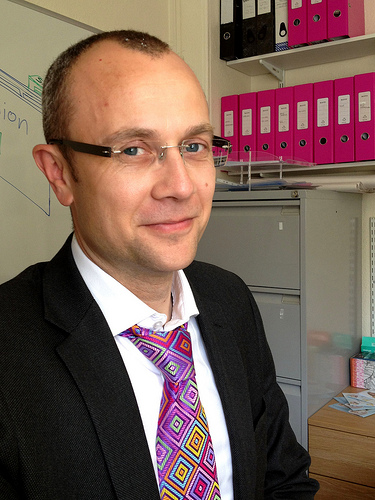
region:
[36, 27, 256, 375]
man posing for a PICTURE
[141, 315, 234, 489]
the tie is multiclored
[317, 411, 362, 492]
the table is wooden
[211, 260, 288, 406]
the coat is black in color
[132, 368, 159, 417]
the shirt is white in color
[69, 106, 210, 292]
the man is smiling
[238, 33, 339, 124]
files are arranged on shelf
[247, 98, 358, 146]
files are oink in color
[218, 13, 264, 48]
files are black incolor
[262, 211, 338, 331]
the cupboard is metallic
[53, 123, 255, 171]
A person wearing black color frame specs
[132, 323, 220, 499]
A person wearing multi color tie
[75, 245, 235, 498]
A person wearing white color shirt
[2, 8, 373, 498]
A person wearing black color suit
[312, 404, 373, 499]
Brown color wooden table kept near the wall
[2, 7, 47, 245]
White color board attached in the wall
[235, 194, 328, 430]
Grey color metal cupboard with racks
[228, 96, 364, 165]
Files kept in the rack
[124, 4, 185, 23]
Cream color wall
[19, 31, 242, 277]
Head of the person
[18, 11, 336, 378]
this is a man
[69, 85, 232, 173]
the man has glasses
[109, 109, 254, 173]
the man has green eyes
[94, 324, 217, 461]
the man has as necktie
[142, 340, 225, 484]
the necktie is colorful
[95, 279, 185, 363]
the man has a collared shirt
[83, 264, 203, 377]
the collared shirt is white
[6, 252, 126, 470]
this is a suit jacket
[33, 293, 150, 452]
the suit jacket is black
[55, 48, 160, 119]
the man is balding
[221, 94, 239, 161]
pink binder on shelf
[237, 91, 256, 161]
pink binder on shelf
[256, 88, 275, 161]
pink binder on shelf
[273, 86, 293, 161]
pink binder on shelf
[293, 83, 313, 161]
pink binder on shelf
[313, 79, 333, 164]
pink binder on shelf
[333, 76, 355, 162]
pink binder on shelf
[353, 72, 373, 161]
pink binder on shelf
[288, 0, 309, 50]
pink binder on shelf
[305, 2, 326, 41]
pink binder on shelf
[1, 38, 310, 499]
the man has glasses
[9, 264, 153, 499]
the coat is black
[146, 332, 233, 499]
the tie is colorfull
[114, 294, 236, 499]
the shirt is white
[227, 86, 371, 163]
the files are on the shelf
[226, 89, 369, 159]
the files are red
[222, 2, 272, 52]
the files are black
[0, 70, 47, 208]
drawing is on the wall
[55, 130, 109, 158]
the frame is black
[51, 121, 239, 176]
the glass is frameles